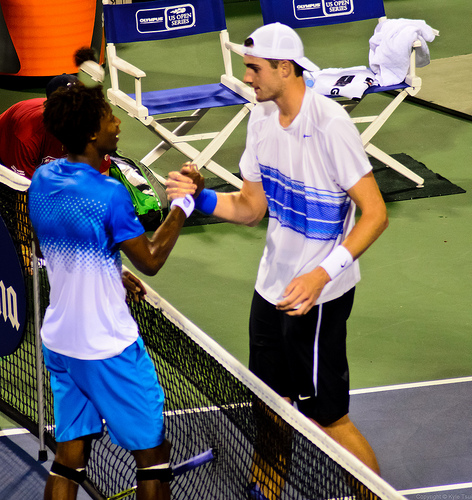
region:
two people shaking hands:
[61, 59, 373, 216]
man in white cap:
[237, 29, 315, 113]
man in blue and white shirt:
[228, 19, 362, 281]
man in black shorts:
[236, 57, 347, 400]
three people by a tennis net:
[14, 52, 400, 390]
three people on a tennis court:
[23, 71, 411, 425]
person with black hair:
[49, 82, 123, 168]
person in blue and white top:
[42, 74, 155, 360]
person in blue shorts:
[42, 73, 164, 462]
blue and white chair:
[96, 4, 242, 124]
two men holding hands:
[49, 31, 309, 248]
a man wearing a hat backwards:
[241, 13, 315, 91]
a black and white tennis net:
[186, 333, 254, 484]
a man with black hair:
[22, 80, 108, 176]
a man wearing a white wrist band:
[316, 234, 366, 285]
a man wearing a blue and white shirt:
[236, 131, 339, 259]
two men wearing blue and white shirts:
[68, 116, 368, 357]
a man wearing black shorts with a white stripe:
[240, 276, 370, 402]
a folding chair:
[117, 4, 241, 165]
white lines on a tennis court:
[417, 348, 457, 497]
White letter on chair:
[166, 13, 172, 24]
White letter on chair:
[170, 13, 174, 23]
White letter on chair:
[177, 13, 182, 23]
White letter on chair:
[176, 10, 184, 23]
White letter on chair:
[187, 7, 193, 20]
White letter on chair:
[169, 18, 175, 26]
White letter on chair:
[137, 15, 145, 23]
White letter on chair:
[141, 16, 146, 22]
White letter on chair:
[150, 15, 158, 23]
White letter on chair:
[156, 15, 163, 25]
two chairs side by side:
[102, 2, 426, 199]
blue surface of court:
[1, 375, 469, 499]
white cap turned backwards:
[243, 20, 318, 102]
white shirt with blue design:
[241, 91, 371, 304]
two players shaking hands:
[30, 22, 388, 496]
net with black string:
[0, 172, 389, 498]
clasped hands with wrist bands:
[169, 161, 216, 211]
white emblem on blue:
[135, 3, 197, 34]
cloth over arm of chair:
[371, 14, 439, 83]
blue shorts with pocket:
[44, 335, 161, 444]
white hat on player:
[247, 22, 320, 79]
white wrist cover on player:
[319, 242, 365, 275]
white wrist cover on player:
[164, 194, 193, 212]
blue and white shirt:
[38, 168, 149, 361]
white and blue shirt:
[244, 99, 359, 302]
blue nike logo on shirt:
[296, 132, 310, 150]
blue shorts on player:
[242, 281, 347, 417]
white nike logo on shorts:
[295, 389, 317, 407]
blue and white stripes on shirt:
[250, 164, 320, 236]